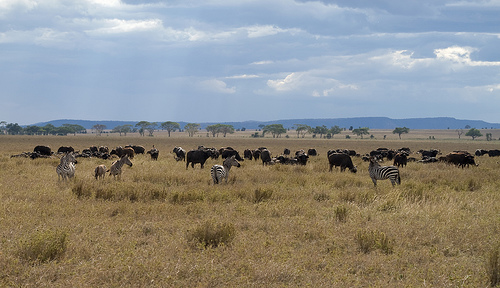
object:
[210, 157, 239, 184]
animals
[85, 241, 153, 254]
grass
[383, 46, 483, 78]
cloud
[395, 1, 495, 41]
sky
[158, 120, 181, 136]
tree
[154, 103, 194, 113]
distance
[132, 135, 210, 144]
brown grass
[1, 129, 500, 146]
plain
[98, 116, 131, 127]
mountains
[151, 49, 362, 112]
light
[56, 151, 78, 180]
zebras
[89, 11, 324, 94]
clouds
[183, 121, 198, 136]
trees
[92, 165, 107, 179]
zebra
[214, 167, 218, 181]
tail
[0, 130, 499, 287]
field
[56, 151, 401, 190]
five zebras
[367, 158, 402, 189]
zebra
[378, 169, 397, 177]
black white stripes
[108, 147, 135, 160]
buffalos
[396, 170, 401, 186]
tail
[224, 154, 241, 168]
head